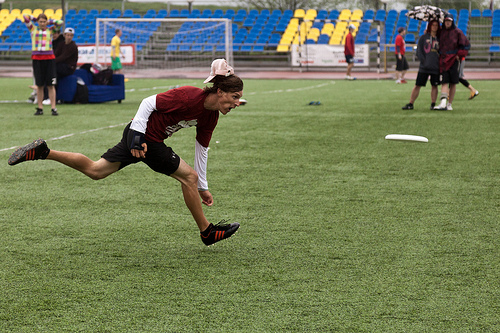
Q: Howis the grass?
A: Green.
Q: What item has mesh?
A: The goal.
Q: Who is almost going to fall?
A: The man.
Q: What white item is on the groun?
A: A line.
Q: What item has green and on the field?
A: Grass.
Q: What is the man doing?
A: Running.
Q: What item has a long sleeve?
A: A shirt.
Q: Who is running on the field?
A: A man.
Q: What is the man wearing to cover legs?
A: Short pants.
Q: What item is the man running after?
A: A frisbee.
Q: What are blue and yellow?
A: Empty seats.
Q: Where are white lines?
A: On the grass.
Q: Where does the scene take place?
A: On a sports field.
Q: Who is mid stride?
A: The man.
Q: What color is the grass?
A: Green.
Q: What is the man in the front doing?
A: Running.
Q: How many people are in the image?
A: Eight.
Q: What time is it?
A: Daytime.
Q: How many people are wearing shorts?
A: Seven.